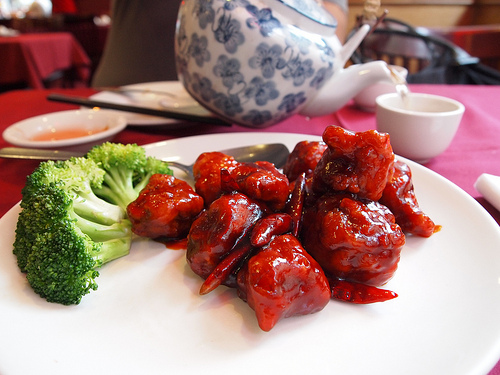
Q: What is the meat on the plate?
A: Chicken.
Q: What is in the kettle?
A: Hot water.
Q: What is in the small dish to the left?
A: Sauce.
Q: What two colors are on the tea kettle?
A: Blue and white.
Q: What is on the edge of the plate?
A: Chopsticks.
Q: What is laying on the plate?
A: Spoon.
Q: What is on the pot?
A: Flowers.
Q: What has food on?
A: A white plate.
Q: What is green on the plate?
A: Broccoli.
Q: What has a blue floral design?
A: The teapot.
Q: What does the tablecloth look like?
A: Pink.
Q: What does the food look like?
A: Red colored food.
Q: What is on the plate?
A: Food items.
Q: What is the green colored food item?
A: Broccoli.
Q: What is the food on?
A: Plate.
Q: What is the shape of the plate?
A: Round.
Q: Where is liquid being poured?
A: Tea cup.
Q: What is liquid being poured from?
A: Tea pot.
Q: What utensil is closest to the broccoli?
A: Spoon.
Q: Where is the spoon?
A: On the plate.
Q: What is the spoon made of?
A: Metal.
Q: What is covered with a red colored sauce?
A: Meat and peppers.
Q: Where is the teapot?
A: Behind the plate.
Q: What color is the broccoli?
A: Green.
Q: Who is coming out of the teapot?
A: Tea.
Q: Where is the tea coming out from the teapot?
A: The spout.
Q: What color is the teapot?
A: Blue and white.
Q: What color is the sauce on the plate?
A: Red.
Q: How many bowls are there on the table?
A: One.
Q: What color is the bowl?
A: White.